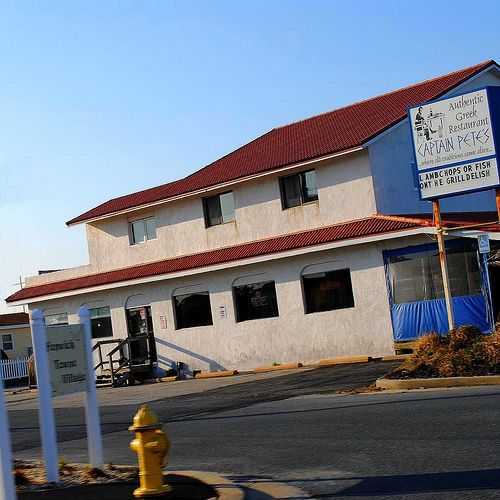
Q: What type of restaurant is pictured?
A: An authentic greek restaurant.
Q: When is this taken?
A: Daytime.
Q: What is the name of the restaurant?
A: Captain Pete's.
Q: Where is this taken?
A: Outside of a restaurant.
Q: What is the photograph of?
A: A restaurant building.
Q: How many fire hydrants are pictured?
A: One.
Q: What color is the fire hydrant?
A: Yellow.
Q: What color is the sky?
A: Blue.